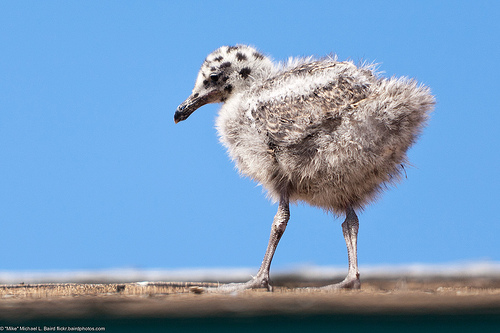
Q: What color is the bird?
A: Grey and black.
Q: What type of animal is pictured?
A: A bird.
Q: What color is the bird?
A: Black and white.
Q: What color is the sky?
A: Blue.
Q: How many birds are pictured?
A: One.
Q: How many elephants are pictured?
A: Zero.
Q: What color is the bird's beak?
A: Black.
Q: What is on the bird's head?
A: Black spots.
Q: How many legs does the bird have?
A: Two.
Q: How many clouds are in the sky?
A: Zero.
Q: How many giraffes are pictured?
A: Zero.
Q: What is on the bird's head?
A: There are spots.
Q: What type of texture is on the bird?
A: It is fuzz.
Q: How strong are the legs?
A: They are frail.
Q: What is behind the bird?
A: The sky.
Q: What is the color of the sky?
A: It's blue.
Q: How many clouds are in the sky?
A: There are zero.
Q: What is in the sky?
A: There is nothing.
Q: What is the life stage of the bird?
A: It is a baby.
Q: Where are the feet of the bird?
A: They are apart.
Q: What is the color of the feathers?
A: It's white.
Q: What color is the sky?
A: Blue.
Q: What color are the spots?
A: Black.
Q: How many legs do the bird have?
A: Two.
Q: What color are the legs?
A: Gray.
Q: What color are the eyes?
A: Black.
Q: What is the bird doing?
A: Standing.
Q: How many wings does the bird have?
A: Two.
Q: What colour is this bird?
A: White, grey, black.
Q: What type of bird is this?
A: Baby bird.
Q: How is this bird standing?
A: On its legs.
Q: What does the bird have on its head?
A: Spots.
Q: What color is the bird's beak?
A: Black.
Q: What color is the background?
A: Blue.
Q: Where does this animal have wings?
A: On its side.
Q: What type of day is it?
A: Afternoon.